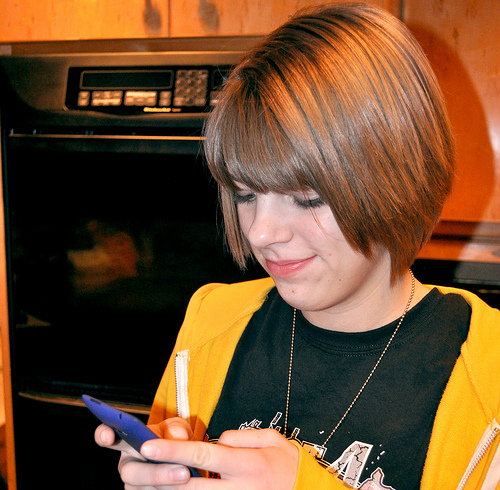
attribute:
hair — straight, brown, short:
[233, 36, 439, 223]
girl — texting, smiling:
[152, 52, 424, 346]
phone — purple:
[74, 381, 210, 477]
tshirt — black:
[248, 312, 404, 487]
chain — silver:
[279, 334, 349, 435]